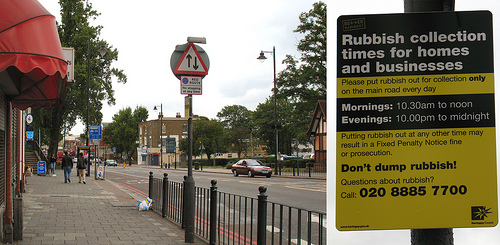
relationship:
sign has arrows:
[173, 40, 211, 90] [182, 47, 207, 79]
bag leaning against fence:
[131, 190, 159, 215] [142, 160, 336, 244]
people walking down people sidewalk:
[77, 152, 88, 183] [56, 187, 150, 241]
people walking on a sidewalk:
[48, 147, 100, 205] [20, 184, 206, 240]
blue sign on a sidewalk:
[89, 125, 101, 142] [16, 144, 246, 243]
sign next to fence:
[152, 22, 242, 210] [132, 136, 276, 243]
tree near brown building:
[163, 105, 239, 200] [136, 113, 225, 167]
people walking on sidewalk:
[60, 152, 75, 184] [0, 157, 221, 243]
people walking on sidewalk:
[77, 152, 88, 183] [0, 157, 221, 243]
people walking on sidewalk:
[60, 152, 75, 184] [43, 185, 119, 237]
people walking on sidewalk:
[77, 152, 88, 183] [43, 185, 119, 237]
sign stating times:
[332, 9, 499, 231] [332, 93, 489, 125]